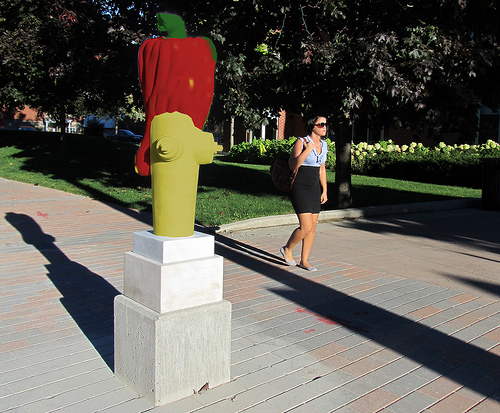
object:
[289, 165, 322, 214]
black skirt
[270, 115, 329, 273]
person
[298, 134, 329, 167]
shirt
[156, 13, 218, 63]
piece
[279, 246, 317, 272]
flats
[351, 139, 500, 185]
wall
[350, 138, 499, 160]
flowers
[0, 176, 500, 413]
walkway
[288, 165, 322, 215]
pants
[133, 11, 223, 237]
fire hydrant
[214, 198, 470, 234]
curb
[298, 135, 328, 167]
top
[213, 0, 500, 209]
tree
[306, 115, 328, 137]
hair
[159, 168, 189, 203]
yellow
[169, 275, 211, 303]
concrete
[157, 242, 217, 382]
blocks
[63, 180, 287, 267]
shadow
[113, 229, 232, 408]
pedestal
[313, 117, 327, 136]
face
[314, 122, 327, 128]
sunglasses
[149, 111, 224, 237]
bottom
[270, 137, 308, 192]
bag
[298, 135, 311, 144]
shoulder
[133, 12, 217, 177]
chili pepper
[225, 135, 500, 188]
plants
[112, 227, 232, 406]
base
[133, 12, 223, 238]
statue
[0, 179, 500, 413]
pathway